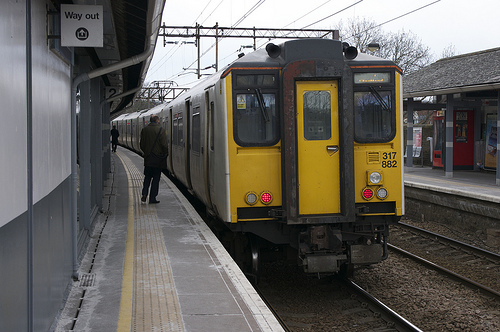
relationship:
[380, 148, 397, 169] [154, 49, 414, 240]
number on front of train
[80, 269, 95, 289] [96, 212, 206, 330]
metal grating on train platform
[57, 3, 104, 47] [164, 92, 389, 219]
sign hanging beside train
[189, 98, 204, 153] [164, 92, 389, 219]
window on train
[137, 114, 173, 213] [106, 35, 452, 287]
man waiting for train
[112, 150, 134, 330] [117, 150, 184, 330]
line along path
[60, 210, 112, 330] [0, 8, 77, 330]
drain along wall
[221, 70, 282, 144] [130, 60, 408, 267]
back window on train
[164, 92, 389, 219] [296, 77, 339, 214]
train has door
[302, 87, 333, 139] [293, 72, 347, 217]
window of door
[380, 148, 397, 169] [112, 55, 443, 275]
number of train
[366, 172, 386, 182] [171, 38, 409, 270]
rear light of train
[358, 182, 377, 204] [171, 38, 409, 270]
rear light of train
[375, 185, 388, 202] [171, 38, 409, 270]
rear light of train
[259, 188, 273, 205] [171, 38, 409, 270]
rear light of train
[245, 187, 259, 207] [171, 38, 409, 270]
rear light of train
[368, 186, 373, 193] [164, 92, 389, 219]
headlight on train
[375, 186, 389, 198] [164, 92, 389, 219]
headlight on train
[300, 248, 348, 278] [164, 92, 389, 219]
stair of train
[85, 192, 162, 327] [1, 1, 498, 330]
line at station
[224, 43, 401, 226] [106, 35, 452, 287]
back of train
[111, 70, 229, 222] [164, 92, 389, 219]
side of train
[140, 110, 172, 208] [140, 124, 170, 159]
man wearing coat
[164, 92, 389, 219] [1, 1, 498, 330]
train pulling into station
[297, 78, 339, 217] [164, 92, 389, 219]
metal door on train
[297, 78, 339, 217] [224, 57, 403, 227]
metal door on front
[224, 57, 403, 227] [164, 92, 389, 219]
front of train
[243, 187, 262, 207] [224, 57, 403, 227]
headlight on front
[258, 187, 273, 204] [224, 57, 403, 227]
headlight on front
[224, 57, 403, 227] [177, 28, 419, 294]
front of train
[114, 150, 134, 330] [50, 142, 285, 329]
stripe painted on platform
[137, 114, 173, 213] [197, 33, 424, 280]
man waiting for train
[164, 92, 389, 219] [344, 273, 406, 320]
train on train tracks